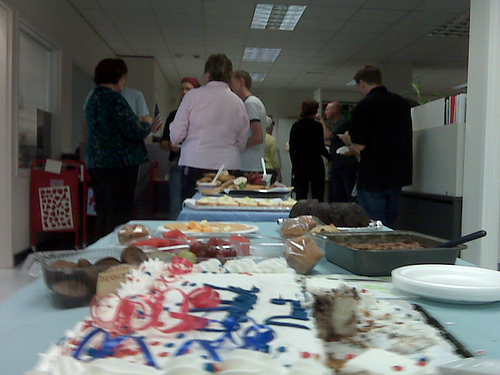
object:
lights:
[250, 3, 306, 31]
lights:
[249, 71, 267, 83]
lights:
[241, 46, 282, 62]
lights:
[427, 14, 473, 39]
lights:
[345, 79, 357, 86]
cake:
[21, 258, 499, 373]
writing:
[263, 293, 310, 331]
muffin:
[282, 236, 324, 275]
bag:
[282, 235, 325, 275]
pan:
[324, 229, 468, 276]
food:
[343, 240, 433, 250]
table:
[0, 218, 499, 374]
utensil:
[431, 229, 487, 248]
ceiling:
[55, 0, 470, 114]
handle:
[434, 229, 487, 249]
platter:
[321, 230, 470, 278]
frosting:
[28, 256, 471, 374]